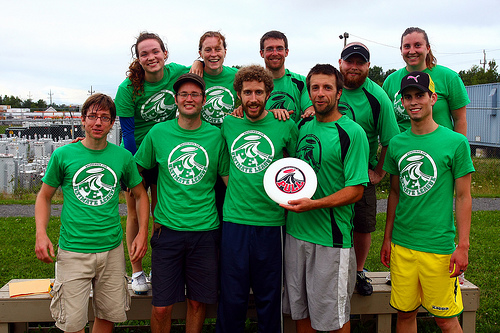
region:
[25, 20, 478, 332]
group of people in similar attire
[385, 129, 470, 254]
green shirt on person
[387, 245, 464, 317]
yellow shorts on man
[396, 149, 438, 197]
symbol in shirt worn by man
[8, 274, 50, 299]
folder on the bench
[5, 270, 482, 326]
bench behind the people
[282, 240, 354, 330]
gray shorts worn by person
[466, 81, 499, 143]
part of building structure in back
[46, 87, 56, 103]
utility pole carrying lines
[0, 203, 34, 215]
paved trail area behind group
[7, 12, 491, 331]
a Frisbee team posing for a picture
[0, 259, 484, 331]
a bench behind the team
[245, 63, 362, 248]
this man is holding a frisbee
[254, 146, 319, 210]
the frisbee is round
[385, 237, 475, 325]
his shorts are yellow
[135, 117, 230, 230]
the uniform is green and white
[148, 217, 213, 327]
his shorts are blue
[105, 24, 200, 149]
a girl leaning forward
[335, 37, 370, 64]
a blue baseball cap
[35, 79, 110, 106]
power lines are distant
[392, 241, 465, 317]
bright yellow shorts with black lightning bolt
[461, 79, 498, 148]
light blue shipping container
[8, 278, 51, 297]
orange piece of paper on the bench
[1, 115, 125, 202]
section of chain link fencing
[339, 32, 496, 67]
power line on the right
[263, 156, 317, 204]
white frisbee with red and black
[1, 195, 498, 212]
gravel walking area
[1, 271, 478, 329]
long wooden bench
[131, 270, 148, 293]
white shoe with a big white flap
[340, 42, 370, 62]
black visor with white Nike swoosh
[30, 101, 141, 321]
man wearing green shirt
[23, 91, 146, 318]
man wearing khaki shorts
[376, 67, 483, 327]
man wearing a cap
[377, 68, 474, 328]
man wearing green shirt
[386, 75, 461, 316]
man wearing yellow shorts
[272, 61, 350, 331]
man holding a frisbee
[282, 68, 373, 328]
man wearing green shirt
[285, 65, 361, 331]
man wearing gray shorts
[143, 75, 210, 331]
man wearing a cap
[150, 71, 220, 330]
man wearing green shirt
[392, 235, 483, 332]
guy is wearing yellow shorts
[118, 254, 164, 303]
girl has on white shoes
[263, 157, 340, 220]
guy is holding a frisbee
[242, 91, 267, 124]
man has a beard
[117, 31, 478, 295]
back row is standing on a bench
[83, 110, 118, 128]
man is wearing glasses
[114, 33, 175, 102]
woman has a ponytail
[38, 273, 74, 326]
man has pocket on side of shorts